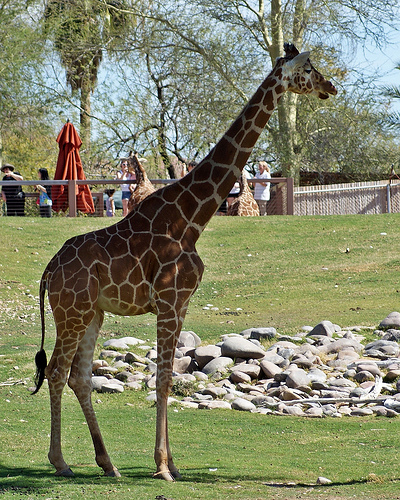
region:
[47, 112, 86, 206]
a orange tent cover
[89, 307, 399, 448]
a pile of rocks on ground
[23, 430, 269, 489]
green grass on the ground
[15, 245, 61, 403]
a giraffe long tail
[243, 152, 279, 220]
a person wearing a long white shirt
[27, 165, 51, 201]
a little girl with long black hair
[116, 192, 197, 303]
a giraffe with brown spots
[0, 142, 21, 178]
a man wearing a hat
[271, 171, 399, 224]
a tall wooden fence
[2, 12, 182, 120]
green trees in back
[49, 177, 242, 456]
This is a giraffe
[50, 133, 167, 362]
The giraffe is white and brown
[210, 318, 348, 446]
This is a group of rocks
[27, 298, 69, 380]
This is a tail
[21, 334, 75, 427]
The tail is black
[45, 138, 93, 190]
This is a an umbrella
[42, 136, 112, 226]
The umbrella is orange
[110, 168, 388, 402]
This is a zoo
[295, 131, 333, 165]
These are old trees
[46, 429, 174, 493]
These are hooves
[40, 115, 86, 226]
UMBRELLA IS IN A CLOSED POSITION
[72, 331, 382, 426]
PILE OF ROCKS IS IN THE FIELD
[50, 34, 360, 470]
GIRAFFE IS TAN AND BROWN IN COLOR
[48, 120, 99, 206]
UMBRELLA IS RED IN COLOR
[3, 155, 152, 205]
MANY PEOPLE ARE LOOKING AT THE GIRAFFES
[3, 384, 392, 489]
GROUND CONSIST OF GREEN GRASS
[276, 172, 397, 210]
WOODEN FENCE IS IN THE BACKGROUND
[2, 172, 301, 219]
GIRAFFE IS IN A FENCED IN AREA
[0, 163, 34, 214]
MAN IS WEARING A TAN HAT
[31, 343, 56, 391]
GIRAFFE HAS A BLACK TAIL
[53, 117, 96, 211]
A closed red umbrella.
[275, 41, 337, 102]
Head of a brown and white spotted giraffe.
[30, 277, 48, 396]
Long brown and white tail with frayed black end on a giraffe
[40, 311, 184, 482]
Four legs of a brown and white spotted giraffe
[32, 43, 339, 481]
Brown and white spotted giraffe.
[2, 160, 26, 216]
A man in mostly black and a safari hat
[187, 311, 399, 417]
Large pile of grey rocks in front of a giraffe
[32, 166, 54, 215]
A black haired woman turned to the left wearing a blue shirt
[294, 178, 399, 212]
A white fence with metal post to the right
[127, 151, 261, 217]
Two giraffes up by the people.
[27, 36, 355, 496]
This is a giraffe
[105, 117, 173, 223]
This is a giraffe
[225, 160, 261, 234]
This is a giraffe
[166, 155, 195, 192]
This is a giraffe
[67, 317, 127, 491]
Leg of a giraffe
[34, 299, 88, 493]
Leg of a giraffe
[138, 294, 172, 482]
Leg of a giraffe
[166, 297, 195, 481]
Leg of a giraffe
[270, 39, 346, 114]
Head of a giraffe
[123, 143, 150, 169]
Head of a giraffe